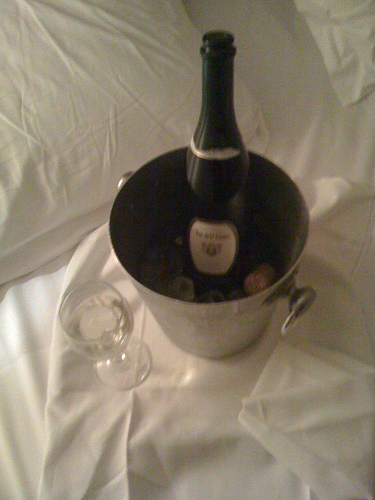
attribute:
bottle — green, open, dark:
[180, 31, 244, 275]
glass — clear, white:
[52, 282, 147, 370]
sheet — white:
[0, 6, 374, 414]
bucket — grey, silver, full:
[110, 139, 324, 367]